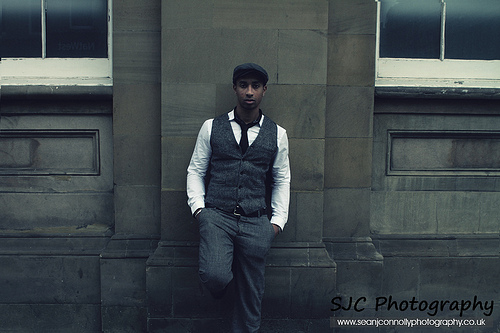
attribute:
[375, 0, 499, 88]
window — shut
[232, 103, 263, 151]
tie — black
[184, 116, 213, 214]
sleeve — white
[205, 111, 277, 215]
vest — grey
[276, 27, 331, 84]
brick — stone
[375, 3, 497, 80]
window — shut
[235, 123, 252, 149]
tie — black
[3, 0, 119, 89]
window — shut